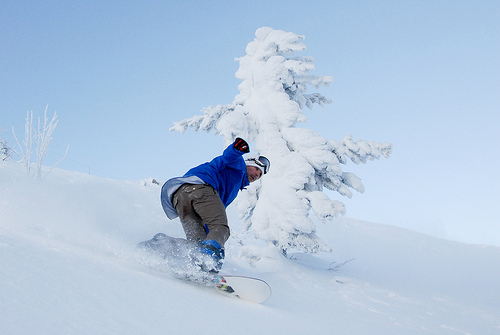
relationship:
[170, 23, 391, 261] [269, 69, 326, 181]
tree covered in snow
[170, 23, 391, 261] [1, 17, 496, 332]
tree covered with snow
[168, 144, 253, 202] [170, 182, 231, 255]
blue jacket over pants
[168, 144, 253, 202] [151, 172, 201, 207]
blue jacket over shirttail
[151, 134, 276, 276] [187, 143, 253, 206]
man in jacket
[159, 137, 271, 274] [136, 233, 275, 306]
man on board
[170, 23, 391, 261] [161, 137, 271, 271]
tree behind man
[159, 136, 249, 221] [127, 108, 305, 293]
blue jacket on person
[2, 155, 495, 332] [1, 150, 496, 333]
snow on ground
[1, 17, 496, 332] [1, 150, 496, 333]
snow on ground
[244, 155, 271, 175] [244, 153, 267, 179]
glasses with hat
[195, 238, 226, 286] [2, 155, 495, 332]
boot in snow